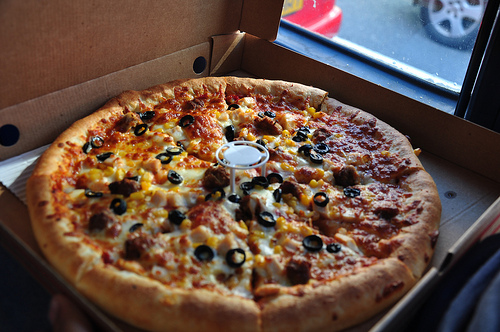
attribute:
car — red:
[280, 0, 347, 40]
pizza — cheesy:
[179, 167, 284, 246]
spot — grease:
[439, 189, 454, 201]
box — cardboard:
[7, 4, 497, 174]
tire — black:
[419, 0, 484, 48]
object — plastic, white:
[215, 141, 272, 195]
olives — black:
[158, 152, 193, 178]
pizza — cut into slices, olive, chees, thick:
[40, 69, 445, 330]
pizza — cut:
[30, 44, 487, 326]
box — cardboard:
[2, 7, 274, 98]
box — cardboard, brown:
[21, 38, 480, 324]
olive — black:
[242, 176, 255, 193]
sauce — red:
[55, 144, 103, 191]